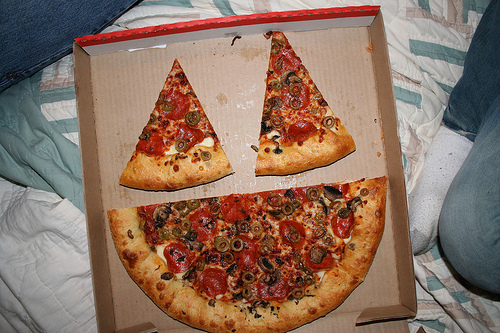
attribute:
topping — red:
[280, 221, 308, 252]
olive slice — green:
[234, 239, 243, 251]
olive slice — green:
[215, 239, 228, 249]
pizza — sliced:
[100, 37, 404, 324]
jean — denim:
[438, 131, 499, 273]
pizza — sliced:
[116, 68, 211, 168]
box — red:
[375, 53, 397, 100]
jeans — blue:
[3, 3, 80, 65]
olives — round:
[288, 96, 303, 110]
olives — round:
[231, 237, 243, 252]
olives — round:
[214, 236, 230, 253]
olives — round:
[184, 111, 201, 126]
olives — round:
[304, 186, 321, 201]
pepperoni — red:
[163, 239, 203, 271]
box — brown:
[86, 31, 428, 329]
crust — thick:
[354, 200, 376, 249]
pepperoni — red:
[283, 117, 323, 147]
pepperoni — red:
[330, 206, 354, 236]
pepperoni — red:
[279, 217, 307, 248]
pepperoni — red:
[229, 246, 263, 269]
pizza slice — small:
[117, 57, 236, 193]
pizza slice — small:
[254, 30, 354, 175]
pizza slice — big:
[106, 174, 388, 331]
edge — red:
[72, 2, 384, 52]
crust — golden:
[105, 127, 386, 331]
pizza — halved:
[100, 172, 390, 332]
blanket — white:
[0, 175, 94, 331]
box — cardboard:
[71, 6, 415, 331]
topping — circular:
[229, 233, 248, 252]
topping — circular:
[213, 234, 230, 256]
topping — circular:
[234, 217, 253, 234]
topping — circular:
[179, 218, 193, 233]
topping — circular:
[241, 267, 257, 284]